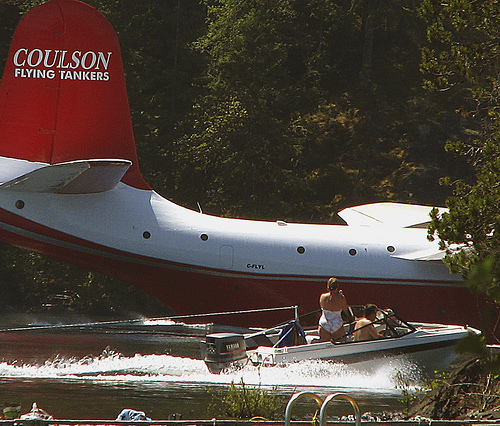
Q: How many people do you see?
A: 2.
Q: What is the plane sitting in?
A: Water.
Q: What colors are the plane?
A: Red and White.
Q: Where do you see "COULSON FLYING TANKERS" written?
A: The tail wing of the plane.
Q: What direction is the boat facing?
A: To the right.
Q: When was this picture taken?
A: During daylight.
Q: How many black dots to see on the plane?
A: 6.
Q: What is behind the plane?
A: Trees.